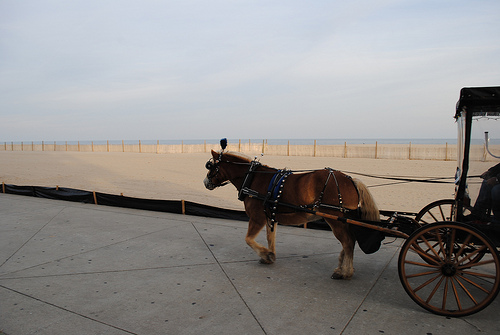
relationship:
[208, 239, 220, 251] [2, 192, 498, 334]
dot on cement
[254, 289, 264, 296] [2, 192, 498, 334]
dot on cement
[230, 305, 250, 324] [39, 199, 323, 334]
dot on cement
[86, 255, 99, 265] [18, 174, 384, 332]
dot on cement